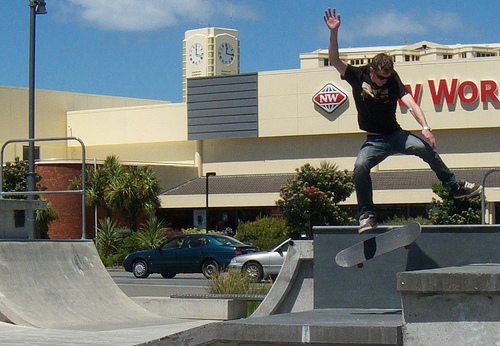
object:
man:
[321, 7, 488, 235]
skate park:
[0, 136, 499, 345]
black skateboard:
[334, 220, 423, 271]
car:
[122, 232, 260, 280]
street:
[104, 268, 278, 298]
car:
[227, 234, 315, 285]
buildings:
[139, 58, 500, 253]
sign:
[308, 83, 348, 117]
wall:
[188, 55, 500, 143]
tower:
[182, 28, 241, 103]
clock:
[216, 42, 237, 66]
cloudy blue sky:
[0, 0, 499, 104]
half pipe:
[0, 240, 197, 330]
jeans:
[353, 126, 461, 219]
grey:
[32, 277, 64, 298]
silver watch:
[422, 124, 431, 131]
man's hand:
[419, 127, 440, 149]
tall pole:
[25, 1, 39, 244]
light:
[36, 0, 48, 17]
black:
[365, 241, 374, 249]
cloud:
[308, 6, 487, 47]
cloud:
[46, 0, 262, 36]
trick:
[321, 6, 489, 269]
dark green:
[213, 245, 230, 253]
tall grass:
[202, 262, 272, 320]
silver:
[267, 255, 281, 262]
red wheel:
[403, 244, 415, 252]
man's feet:
[351, 214, 382, 235]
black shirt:
[340, 65, 416, 136]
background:
[1, 0, 500, 346]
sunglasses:
[373, 71, 391, 79]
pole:
[204, 171, 212, 231]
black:
[210, 173, 213, 175]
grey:
[336, 258, 344, 266]